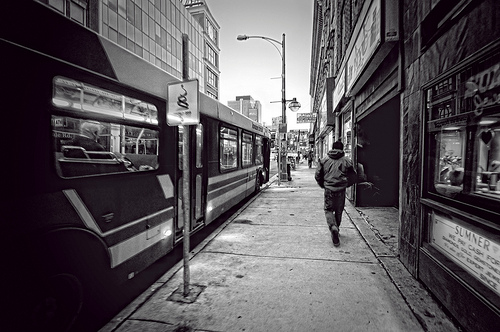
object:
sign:
[174, 82, 190, 113]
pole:
[177, 33, 193, 298]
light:
[235, 32, 253, 42]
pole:
[276, 32, 289, 185]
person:
[314, 141, 358, 248]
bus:
[0, 1, 276, 326]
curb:
[109, 264, 185, 331]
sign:
[424, 213, 500, 293]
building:
[308, 0, 498, 331]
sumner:
[452, 226, 491, 254]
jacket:
[312, 148, 362, 192]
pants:
[321, 187, 346, 228]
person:
[72, 120, 115, 160]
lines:
[198, 248, 382, 266]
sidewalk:
[100, 163, 460, 330]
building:
[44, 1, 221, 102]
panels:
[115, 11, 131, 38]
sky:
[205, 0, 316, 100]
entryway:
[352, 92, 412, 234]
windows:
[427, 120, 465, 200]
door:
[176, 107, 194, 239]